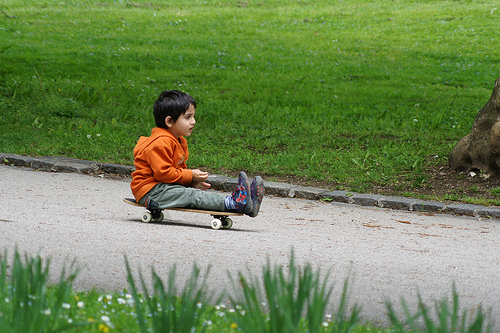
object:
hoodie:
[131, 127, 193, 204]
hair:
[153, 90, 195, 130]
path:
[0, 152, 499, 332]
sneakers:
[235, 171, 255, 216]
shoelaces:
[233, 184, 240, 199]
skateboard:
[122, 197, 244, 229]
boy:
[130, 89, 265, 217]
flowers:
[96, 133, 101, 136]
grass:
[483, 188, 498, 196]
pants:
[140, 181, 230, 212]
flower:
[411, 118, 420, 123]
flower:
[77, 299, 85, 307]